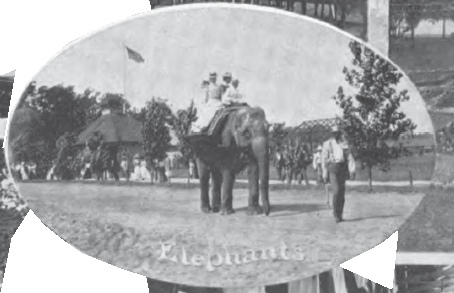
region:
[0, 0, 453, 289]
the photo is black and white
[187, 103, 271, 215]
an elephant is walking along the road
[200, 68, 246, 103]
four people are atop the elephant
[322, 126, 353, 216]
a man is in front of the elphant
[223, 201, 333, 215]
the elephant is casting a shadow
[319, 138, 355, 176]
the man is wearing a white shirt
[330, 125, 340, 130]
the man is wearing a hat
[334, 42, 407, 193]
a tall tree is in the background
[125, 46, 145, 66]
the flag is fluttering in the sky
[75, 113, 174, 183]
a building is in the background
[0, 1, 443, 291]
Oval photography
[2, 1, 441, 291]
Photo is black and white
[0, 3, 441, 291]
Photo depicts people sit in an elephant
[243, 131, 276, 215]
Trunk of elephant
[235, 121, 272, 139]
Eyes of elephant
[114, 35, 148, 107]
American flag flying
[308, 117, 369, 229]
Man walking in a field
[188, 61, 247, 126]
People sit on back of an elephant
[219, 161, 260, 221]
Front legs of elephant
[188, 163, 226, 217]
Back legs of elephant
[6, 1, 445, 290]
White and black picture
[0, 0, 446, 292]
Frame of picture is oval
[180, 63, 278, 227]
Four people sitting on an elephant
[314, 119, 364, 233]
Person walking in front of elephant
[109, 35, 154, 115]
American flag on top a cottage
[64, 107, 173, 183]
Cottage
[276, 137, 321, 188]
People walking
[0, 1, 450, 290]
Word on picture is "Elephants"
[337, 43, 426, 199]
Tree on the right side of picture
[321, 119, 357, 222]
Man walking before an elephant.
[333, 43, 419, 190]
Tall tree lining walkway.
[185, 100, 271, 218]
Elephant walking behind a man.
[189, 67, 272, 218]
Four people riding atop an elephant.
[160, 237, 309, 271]
The word 'Elephants' in playful font.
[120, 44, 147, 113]
Flag waving in the wind on a pole.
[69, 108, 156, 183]
White building partially hidden by trees.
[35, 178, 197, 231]
Section of a flat grass field.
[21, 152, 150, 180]
People walking along the walkway.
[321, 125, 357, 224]
Man with hat on walking on grass.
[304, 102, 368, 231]
Man walking in front of an elephant.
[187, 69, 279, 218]
People riding an elephant.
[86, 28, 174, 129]
An American flag on a pole.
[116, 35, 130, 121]
A pole holding an American flag.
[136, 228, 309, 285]
The word Elephant's printed on the picture.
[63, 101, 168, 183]
A building in the background.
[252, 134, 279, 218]
An elephant trunk hanging to the ground.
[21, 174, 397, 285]
An open field with cut grass.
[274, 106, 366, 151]
A building being constructed in the distance.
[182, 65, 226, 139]
A woman wearing a white dress.